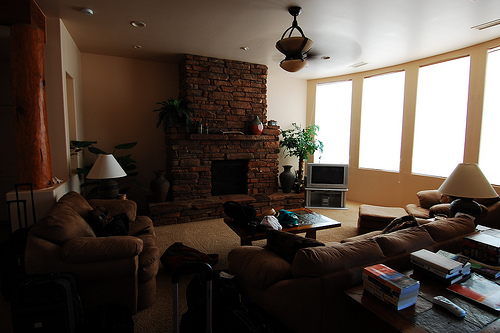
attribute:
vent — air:
[472, 17, 499, 32]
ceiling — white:
[49, 2, 496, 79]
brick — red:
[174, 66, 309, 223]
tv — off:
[304, 162, 347, 187]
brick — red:
[190, 151, 200, 156]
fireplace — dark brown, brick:
[159, 50, 304, 208]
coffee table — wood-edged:
[219, 207, 341, 240]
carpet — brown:
[173, 220, 222, 246]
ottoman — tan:
[355, 202, 408, 232]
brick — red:
[225, 67, 241, 75]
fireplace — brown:
[145, 51, 307, 227]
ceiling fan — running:
[241, 2, 366, 89]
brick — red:
[204, 47, 243, 96]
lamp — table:
[435, 161, 499, 231]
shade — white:
[435, 161, 498, 201]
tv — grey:
[306, 162, 349, 188]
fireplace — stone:
[157, 52, 299, 218]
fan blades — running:
[248, 23, 364, 85]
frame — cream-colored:
[300, 39, 498, 212]